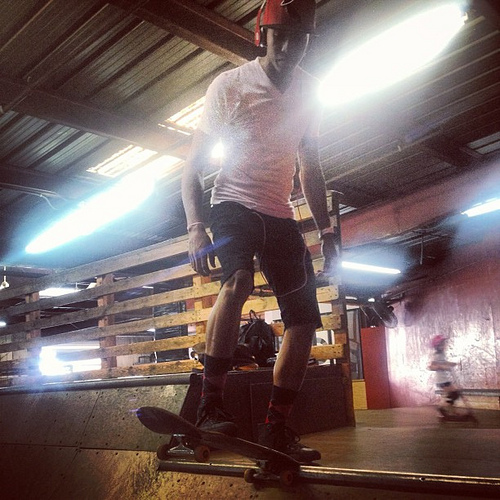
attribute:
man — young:
[156, 11, 351, 446]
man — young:
[167, 0, 377, 427]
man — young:
[175, 27, 370, 435]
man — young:
[162, 21, 349, 399]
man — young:
[146, 0, 406, 423]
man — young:
[140, 17, 319, 392]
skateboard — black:
[121, 395, 412, 495]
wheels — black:
[148, 430, 261, 490]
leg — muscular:
[175, 264, 277, 399]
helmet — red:
[244, 0, 306, 27]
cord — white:
[232, 210, 284, 260]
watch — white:
[166, 215, 205, 239]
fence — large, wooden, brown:
[64, 235, 316, 419]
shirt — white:
[191, 32, 358, 214]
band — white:
[175, 219, 218, 246]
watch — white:
[306, 223, 365, 250]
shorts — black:
[188, 194, 358, 335]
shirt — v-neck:
[188, 68, 343, 239]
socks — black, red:
[155, 358, 325, 487]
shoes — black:
[138, 381, 268, 453]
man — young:
[111, 11, 418, 468]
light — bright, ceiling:
[52, 144, 191, 270]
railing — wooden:
[58, 261, 213, 389]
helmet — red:
[238, 0, 360, 41]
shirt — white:
[215, 55, 365, 245]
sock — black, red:
[257, 380, 301, 421]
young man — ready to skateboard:
[212, 12, 332, 338]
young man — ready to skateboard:
[207, 20, 410, 363]